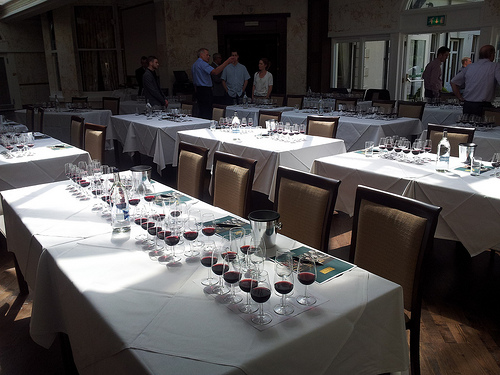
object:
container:
[247, 209, 283, 257]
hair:
[437, 46, 451, 59]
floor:
[0, 232, 500, 374]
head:
[478, 44, 494, 61]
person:
[450, 44, 500, 116]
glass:
[296, 256, 318, 305]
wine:
[298, 272, 316, 286]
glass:
[274, 263, 295, 315]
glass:
[238, 264, 259, 314]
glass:
[201, 240, 220, 285]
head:
[197, 48, 210, 62]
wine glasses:
[128, 193, 141, 217]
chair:
[177, 140, 210, 197]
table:
[0, 170, 401, 375]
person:
[140, 55, 169, 109]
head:
[147, 57, 161, 70]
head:
[259, 58, 268, 70]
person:
[252, 59, 273, 99]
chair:
[212, 151, 258, 217]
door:
[401, 33, 431, 102]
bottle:
[436, 128, 452, 173]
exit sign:
[425, 14, 446, 26]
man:
[221, 50, 249, 105]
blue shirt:
[192, 58, 215, 87]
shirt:
[253, 71, 273, 97]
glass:
[164, 225, 183, 267]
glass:
[250, 270, 271, 326]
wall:
[404, 0, 500, 32]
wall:
[159, 3, 307, 98]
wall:
[329, 0, 406, 34]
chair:
[347, 184, 442, 375]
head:
[437, 46, 450, 62]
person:
[422, 46, 451, 98]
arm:
[205, 63, 228, 76]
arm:
[143, 81, 164, 100]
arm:
[267, 75, 274, 95]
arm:
[450, 69, 466, 98]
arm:
[431, 68, 439, 92]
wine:
[412, 150, 419, 155]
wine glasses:
[201, 213, 216, 246]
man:
[190, 48, 237, 121]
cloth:
[0, 169, 409, 375]